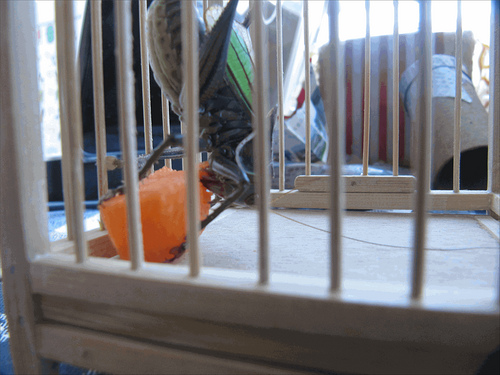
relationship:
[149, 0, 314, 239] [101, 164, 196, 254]
bug eating food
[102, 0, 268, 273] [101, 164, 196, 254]
bug holding food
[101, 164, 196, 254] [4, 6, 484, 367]
food in cage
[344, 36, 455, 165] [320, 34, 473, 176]
strips on chair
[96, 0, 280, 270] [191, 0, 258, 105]
bug has green wing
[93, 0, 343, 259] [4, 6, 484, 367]
bug inside cage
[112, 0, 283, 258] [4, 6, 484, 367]
bug inside cage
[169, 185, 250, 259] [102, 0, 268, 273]
leg on bug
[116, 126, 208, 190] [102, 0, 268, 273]
leg on bug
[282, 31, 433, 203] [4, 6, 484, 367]
door on cage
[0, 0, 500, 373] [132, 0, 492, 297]
insect inside of cage